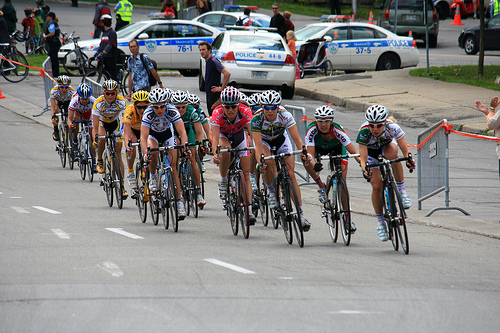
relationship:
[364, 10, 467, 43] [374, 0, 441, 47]
traffic cones around an suv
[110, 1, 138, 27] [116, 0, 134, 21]
officer wearing a yellow vest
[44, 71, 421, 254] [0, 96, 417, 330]
bicyclists on road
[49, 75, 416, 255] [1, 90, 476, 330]
alert bicyclists on road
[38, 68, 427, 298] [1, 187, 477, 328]
alert bicyclists riding on road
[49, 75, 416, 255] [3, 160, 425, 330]
alert bicyclists riding on road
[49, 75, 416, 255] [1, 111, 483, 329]
alert bicyclists riding roadway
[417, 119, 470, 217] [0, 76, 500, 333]
barricade in road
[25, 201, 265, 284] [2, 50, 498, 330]
lines are on road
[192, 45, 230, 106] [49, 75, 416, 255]
man watching alert bicyclists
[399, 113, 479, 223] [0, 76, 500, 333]
barricade on road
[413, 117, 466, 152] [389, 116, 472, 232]
tape on barricade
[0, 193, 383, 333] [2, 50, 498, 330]
lines are on road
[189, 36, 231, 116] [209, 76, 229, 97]
man has hands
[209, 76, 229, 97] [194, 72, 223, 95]
hands are on hips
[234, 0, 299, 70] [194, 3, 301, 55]
people behind car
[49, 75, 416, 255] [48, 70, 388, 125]
alert bicyclists wearing helmets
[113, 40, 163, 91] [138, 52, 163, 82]
man wearing backpack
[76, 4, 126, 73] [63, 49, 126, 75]
man with bicycle